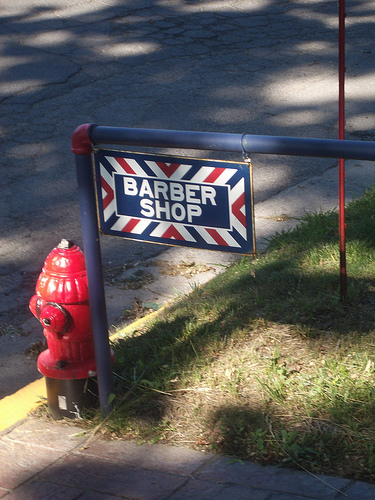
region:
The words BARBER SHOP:
[120, 176, 216, 223]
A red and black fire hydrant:
[29, 237, 100, 418]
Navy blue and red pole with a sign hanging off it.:
[68, 121, 372, 416]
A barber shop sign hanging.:
[93, 148, 254, 257]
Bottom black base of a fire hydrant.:
[43, 373, 101, 418]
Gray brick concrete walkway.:
[1, 417, 373, 499]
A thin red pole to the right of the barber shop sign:
[335, 0, 348, 305]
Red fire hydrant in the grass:
[29, 239, 96, 416]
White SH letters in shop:
[138, 196, 171, 222]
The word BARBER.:
[122, 175, 219, 206]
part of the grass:
[284, 400, 301, 419]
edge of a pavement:
[130, 323, 142, 339]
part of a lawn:
[249, 383, 262, 411]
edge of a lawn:
[132, 420, 142, 437]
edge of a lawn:
[199, 350, 225, 405]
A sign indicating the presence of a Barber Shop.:
[93, 148, 253, 257]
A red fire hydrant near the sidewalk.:
[27, 237, 115, 421]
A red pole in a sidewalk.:
[337, 0, 345, 313]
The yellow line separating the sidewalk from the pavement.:
[0, 305, 164, 431]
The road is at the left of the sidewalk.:
[0, 0, 374, 402]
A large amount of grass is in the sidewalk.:
[25, 189, 373, 485]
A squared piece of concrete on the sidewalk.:
[0, 414, 373, 498]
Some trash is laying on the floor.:
[105, 256, 216, 320]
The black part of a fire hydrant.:
[44, 377, 97, 421]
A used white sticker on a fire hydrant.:
[57, 394, 66, 409]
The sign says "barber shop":
[94, 154, 256, 250]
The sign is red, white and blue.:
[72, 144, 261, 262]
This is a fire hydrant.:
[21, 236, 114, 390]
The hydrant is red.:
[23, 209, 112, 396]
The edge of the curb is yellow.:
[7, 375, 49, 432]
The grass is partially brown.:
[163, 295, 341, 456]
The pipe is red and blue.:
[58, 123, 130, 406]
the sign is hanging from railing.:
[68, 93, 268, 272]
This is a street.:
[57, 14, 300, 129]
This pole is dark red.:
[327, 158, 365, 310]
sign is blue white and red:
[84, 146, 267, 255]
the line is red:
[198, 165, 220, 187]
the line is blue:
[222, 231, 252, 246]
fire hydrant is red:
[25, 195, 164, 383]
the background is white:
[142, 158, 165, 180]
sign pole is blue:
[77, 110, 369, 154]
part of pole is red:
[52, 105, 101, 162]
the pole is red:
[317, 23, 370, 347]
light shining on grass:
[177, 318, 330, 445]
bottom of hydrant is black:
[37, 374, 103, 412]